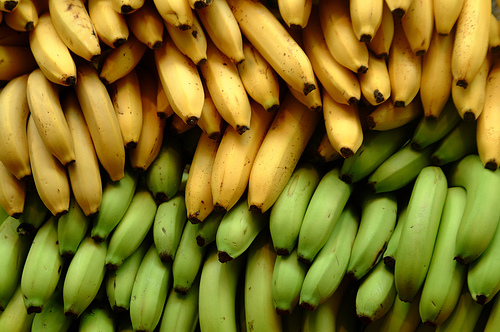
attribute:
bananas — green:
[1, 0, 498, 330]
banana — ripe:
[242, 3, 327, 98]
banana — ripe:
[246, 107, 311, 228]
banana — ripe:
[448, 2, 490, 94]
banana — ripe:
[154, 32, 219, 130]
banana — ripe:
[72, 67, 140, 190]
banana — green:
[0, 210, 56, 313]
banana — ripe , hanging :
[322, 90, 364, 158]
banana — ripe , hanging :
[475, 50, 499, 164]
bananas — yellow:
[3, 7, 483, 149]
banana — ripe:
[153, 42, 207, 128]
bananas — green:
[189, 240, 307, 330]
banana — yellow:
[44, 0, 104, 65]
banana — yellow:
[161, 19, 207, 64]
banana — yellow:
[152, 0, 193, 30]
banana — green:
[395, 163, 448, 300]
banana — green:
[346, 194, 397, 283]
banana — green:
[298, 168, 352, 264]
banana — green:
[353, 260, 397, 322]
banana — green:
[217, 195, 261, 262]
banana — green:
[152, 197, 182, 262]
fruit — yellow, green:
[142, 58, 384, 330]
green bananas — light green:
[0, 219, 500, 330]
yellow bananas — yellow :
[7, 4, 498, 201]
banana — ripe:
[244, 103, 315, 220]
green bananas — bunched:
[0, 101, 498, 329]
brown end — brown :
[450, 72, 472, 93]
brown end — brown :
[302, 81, 316, 97]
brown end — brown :
[450, 251, 469, 271]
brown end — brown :
[20, 299, 41, 317]